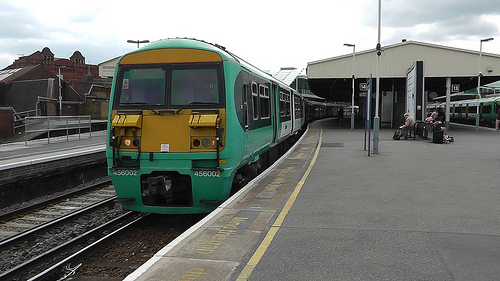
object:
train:
[102, 34, 359, 216]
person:
[391, 111, 417, 142]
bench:
[397, 119, 421, 141]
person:
[424, 110, 453, 143]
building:
[0, 44, 109, 139]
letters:
[192, 247, 215, 255]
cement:
[117, 115, 500, 281]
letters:
[214, 170, 224, 178]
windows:
[166, 61, 226, 108]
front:
[104, 30, 233, 216]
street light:
[341, 42, 360, 131]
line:
[230, 122, 325, 281]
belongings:
[390, 128, 406, 141]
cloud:
[356, 0, 499, 29]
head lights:
[197, 135, 214, 149]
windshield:
[115, 64, 227, 111]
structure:
[272, 66, 307, 87]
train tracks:
[0, 209, 158, 281]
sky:
[2, 0, 499, 72]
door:
[269, 80, 284, 144]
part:
[42, 222, 107, 257]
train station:
[0, 36, 499, 279]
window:
[250, 80, 261, 121]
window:
[257, 83, 274, 122]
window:
[278, 91, 295, 118]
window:
[294, 93, 304, 121]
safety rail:
[23, 113, 97, 146]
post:
[405, 57, 427, 137]